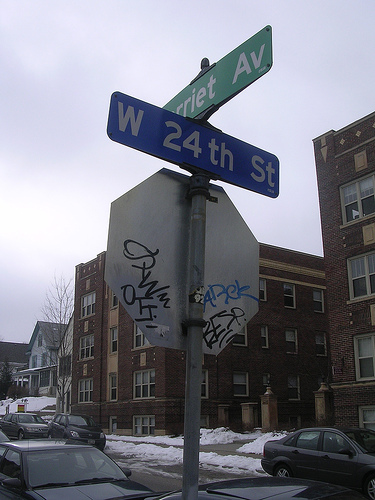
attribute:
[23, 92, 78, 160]
sky — blue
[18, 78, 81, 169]
sky — blue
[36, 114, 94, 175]
sky — blue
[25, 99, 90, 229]
sky — blue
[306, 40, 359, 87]
sky — blue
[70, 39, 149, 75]
sky — blue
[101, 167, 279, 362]
sign — stop 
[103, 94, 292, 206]
blue sign — a street sign, white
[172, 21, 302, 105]
green sign — white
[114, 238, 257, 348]
grafitti — black, blue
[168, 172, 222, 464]
pole — silver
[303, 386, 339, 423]
stone columns — stone 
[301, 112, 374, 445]
building — four-story, red, brick 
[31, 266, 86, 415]
tree — bare 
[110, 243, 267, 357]
graffiti — black 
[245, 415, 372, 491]
car — black , parked , grey 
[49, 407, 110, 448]
suv — black, parked 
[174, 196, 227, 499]
pole — metal 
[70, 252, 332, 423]
building — multi story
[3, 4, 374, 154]
sky — gray , cloudy 